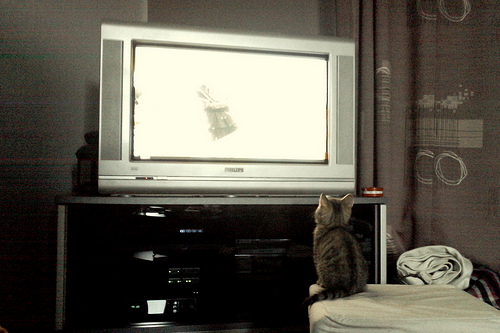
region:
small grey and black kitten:
[310, 189, 372, 306]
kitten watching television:
[96, 15, 376, 302]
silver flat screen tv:
[96, 20, 361, 205]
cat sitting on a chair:
[307, 190, 377, 330]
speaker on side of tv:
[98, 36, 120, 167]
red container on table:
[359, 185, 384, 197]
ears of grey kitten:
[319, 191, 356, 208]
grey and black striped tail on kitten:
[307, 288, 353, 306]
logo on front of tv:
[222, 165, 247, 173]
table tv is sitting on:
[60, 190, 396, 285]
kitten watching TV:
[90, 15, 380, 303]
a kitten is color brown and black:
[294, 183, 378, 314]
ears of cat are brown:
[316, 185, 356, 209]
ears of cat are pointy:
[316, 185, 353, 207]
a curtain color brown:
[340, 9, 492, 251]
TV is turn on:
[82, 14, 367, 199]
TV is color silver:
[90, 13, 367, 204]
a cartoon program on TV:
[134, 48, 319, 153]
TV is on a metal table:
[50, 173, 391, 278]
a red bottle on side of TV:
[360, 180, 390, 202]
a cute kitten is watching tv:
[91, 20, 368, 307]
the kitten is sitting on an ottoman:
[295, 188, 365, 305]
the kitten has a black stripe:
[337, 228, 362, 300]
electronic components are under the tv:
[58, 195, 383, 331]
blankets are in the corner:
[397, 238, 499, 309]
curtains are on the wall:
[338, 1, 498, 269]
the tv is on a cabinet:
[54, 23, 390, 332]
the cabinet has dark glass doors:
[61, 201, 378, 331]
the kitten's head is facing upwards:
[311, 188, 360, 232]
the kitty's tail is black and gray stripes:
[303, 286, 345, 308]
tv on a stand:
[96, 17, 361, 182]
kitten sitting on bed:
[304, 184, 371, 291]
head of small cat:
[309, 186, 353, 225]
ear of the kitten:
[332, 184, 355, 205]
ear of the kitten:
[315, 192, 330, 205]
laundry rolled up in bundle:
[385, 240, 467, 295]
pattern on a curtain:
[425, 136, 475, 201]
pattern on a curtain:
[425, 87, 470, 123]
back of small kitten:
[337, 240, 358, 295]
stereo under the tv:
[143, 236, 212, 313]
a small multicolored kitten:
[304, 192, 371, 308]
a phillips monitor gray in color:
[91, 21, 361, 200]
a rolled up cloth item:
[390, 238, 476, 296]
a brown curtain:
[353, 4, 498, 257]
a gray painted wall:
[1, 2, 85, 132]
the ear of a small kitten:
[317, 191, 329, 206]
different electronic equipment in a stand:
[78, 206, 301, 331]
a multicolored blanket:
[470, 269, 499, 304]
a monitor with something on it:
[91, 20, 360, 197]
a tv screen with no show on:
[89, 18, 361, 200]